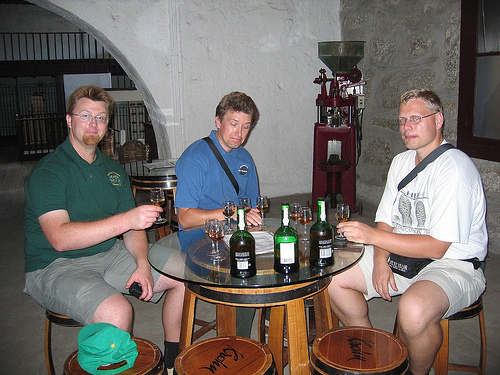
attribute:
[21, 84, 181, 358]
man — seated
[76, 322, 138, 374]
baseball hat — green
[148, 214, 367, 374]
table — round , glass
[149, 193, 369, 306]
table — wooden 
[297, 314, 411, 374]
stool — brown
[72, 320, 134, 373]
cap — Green 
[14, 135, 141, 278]
t-shirt — in color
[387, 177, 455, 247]
shirt — white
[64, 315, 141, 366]
hat — green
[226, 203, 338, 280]
bottles — green 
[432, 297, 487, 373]
stool — wooden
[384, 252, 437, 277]
fanny pack — black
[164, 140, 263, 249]
shirt — blue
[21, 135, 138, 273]
shirt — green 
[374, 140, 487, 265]
shirt — gray 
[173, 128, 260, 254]
shirt — blue 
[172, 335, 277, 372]
stool — empty, wooden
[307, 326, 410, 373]
stool — empty, wooden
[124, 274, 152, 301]
object — black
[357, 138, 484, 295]
shirt — white